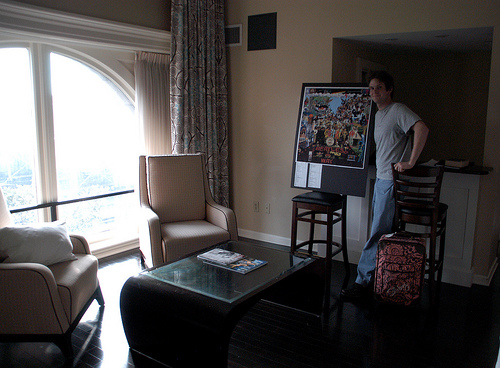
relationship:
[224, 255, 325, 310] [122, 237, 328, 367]
edge of table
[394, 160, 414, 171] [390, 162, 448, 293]
hand on stool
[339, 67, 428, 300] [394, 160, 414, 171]
man has hand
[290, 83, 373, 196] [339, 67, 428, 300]
board beside man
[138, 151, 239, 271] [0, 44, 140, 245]
chair on right of window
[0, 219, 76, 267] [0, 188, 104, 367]
pillow on chair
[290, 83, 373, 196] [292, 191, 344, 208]
board on seat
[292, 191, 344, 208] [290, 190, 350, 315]
seat on stool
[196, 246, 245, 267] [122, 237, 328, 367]
magazine on table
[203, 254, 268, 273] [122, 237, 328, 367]
magazine on table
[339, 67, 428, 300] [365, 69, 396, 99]
man has hair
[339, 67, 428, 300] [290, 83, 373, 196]
man holding art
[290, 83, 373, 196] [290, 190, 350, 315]
art on stool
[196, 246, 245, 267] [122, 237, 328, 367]
magazine lays on table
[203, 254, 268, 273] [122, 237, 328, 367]
magazine lays on table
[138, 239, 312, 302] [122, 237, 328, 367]
top on table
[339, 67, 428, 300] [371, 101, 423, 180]
man wearing part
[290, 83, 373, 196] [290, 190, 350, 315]
photograph resting on stool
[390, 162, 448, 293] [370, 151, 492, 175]
stool under counter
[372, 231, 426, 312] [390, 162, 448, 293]
bag by stool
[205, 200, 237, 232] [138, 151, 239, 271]
arm on chair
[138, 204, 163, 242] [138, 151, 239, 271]
arm on chair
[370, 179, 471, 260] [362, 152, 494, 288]
molding on bar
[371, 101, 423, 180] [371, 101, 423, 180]
part of part